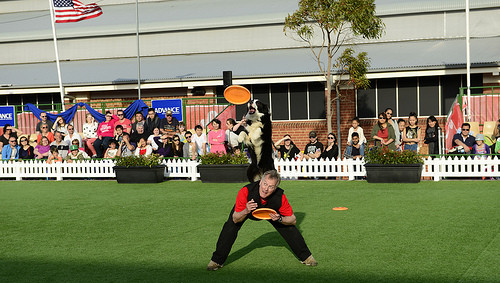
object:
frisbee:
[252, 208, 278, 220]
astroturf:
[0, 178, 500, 283]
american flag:
[55, 1, 104, 23]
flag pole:
[47, 1, 70, 114]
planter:
[199, 164, 256, 183]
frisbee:
[223, 84, 253, 105]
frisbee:
[332, 206, 349, 210]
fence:
[0, 154, 500, 181]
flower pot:
[363, 162, 424, 183]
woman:
[33, 136, 50, 159]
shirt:
[34, 144, 50, 158]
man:
[205, 169, 321, 272]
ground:
[0, 176, 500, 278]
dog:
[238, 99, 278, 183]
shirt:
[234, 186, 293, 216]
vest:
[244, 180, 285, 221]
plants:
[114, 154, 164, 168]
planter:
[112, 166, 169, 184]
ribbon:
[23, 100, 149, 125]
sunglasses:
[462, 128, 470, 131]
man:
[450, 123, 476, 159]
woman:
[371, 112, 396, 152]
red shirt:
[377, 127, 387, 141]